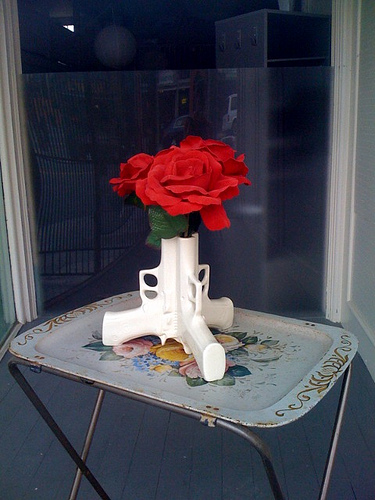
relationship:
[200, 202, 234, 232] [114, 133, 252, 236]
petal on flower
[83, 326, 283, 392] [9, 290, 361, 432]
image on tray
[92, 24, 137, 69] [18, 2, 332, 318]
light behind window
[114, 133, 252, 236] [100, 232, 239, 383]
flower in vase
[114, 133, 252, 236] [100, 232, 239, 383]
flower above vase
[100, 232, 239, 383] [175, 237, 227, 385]
vase shaped like gun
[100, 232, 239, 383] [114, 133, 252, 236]
vase below flower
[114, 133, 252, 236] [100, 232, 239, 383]
flower on vase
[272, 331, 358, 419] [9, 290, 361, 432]
design on tray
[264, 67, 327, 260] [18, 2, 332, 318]
shadow on window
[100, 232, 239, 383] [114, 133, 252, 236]
vase holding flower